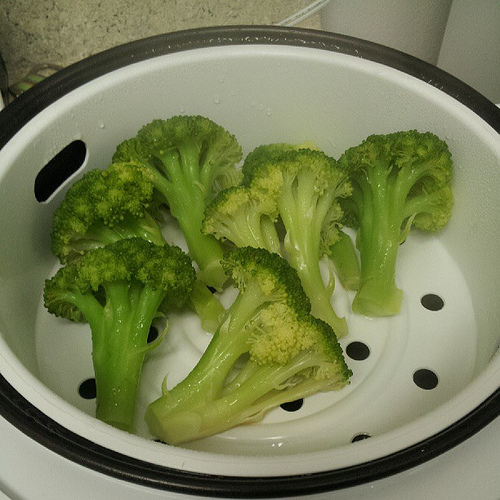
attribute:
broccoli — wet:
[36, 102, 468, 414]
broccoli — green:
[49, 234, 181, 416]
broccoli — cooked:
[332, 114, 458, 324]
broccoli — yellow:
[144, 241, 364, 448]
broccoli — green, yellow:
[335, 128, 454, 315]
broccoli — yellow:
[112, 113, 241, 290]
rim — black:
[163, 22, 401, 61]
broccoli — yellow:
[42, 234, 198, 438]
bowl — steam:
[6, 42, 498, 482]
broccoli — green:
[185, 136, 415, 377]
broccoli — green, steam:
[38, 115, 455, 445]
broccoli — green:
[54, 173, 173, 275]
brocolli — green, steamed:
[140, 124, 454, 374]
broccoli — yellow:
[200, 148, 349, 259]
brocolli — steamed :
[330, 115, 485, 336]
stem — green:
[348, 208, 409, 320]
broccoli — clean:
[44, 245, 204, 443]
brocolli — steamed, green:
[50, 134, 461, 404]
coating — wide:
[0, 43, 498, 374]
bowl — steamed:
[2, 22, 478, 471]